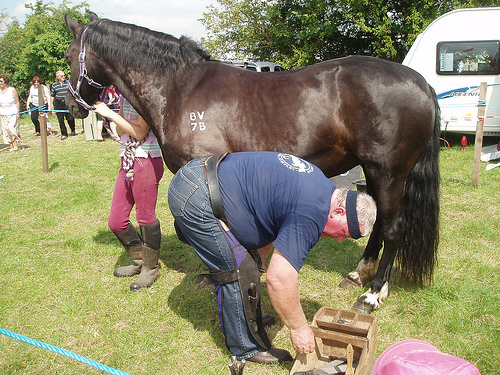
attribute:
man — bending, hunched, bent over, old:
[169, 150, 378, 365]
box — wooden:
[292, 305, 379, 374]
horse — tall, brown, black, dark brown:
[64, 9, 442, 312]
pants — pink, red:
[109, 154, 165, 232]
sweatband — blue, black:
[345, 189, 362, 241]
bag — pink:
[375, 341, 484, 374]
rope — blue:
[435, 82, 499, 107]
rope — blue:
[0, 105, 72, 116]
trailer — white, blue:
[394, 8, 500, 143]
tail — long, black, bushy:
[391, 83, 439, 290]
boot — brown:
[112, 222, 146, 278]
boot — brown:
[128, 218, 161, 297]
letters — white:
[188, 110, 209, 134]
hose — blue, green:
[0, 324, 133, 374]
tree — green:
[196, 1, 499, 73]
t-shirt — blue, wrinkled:
[219, 150, 335, 272]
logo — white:
[277, 150, 314, 174]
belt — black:
[206, 152, 231, 223]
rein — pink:
[65, 21, 106, 115]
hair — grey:
[338, 187, 377, 238]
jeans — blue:
[166, 157, 267, 360]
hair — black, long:
[78, 19, 208, 77]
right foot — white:
[341, 206, 385, 290]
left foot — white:
[352, 239, 400, 313]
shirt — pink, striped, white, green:
[122, 88, 164, 160]